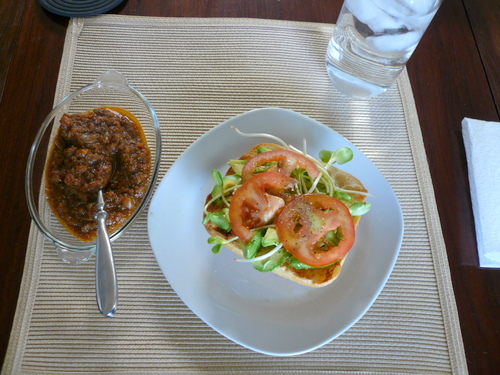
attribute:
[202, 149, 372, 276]
vegetable — green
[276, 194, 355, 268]
tomatoe — sliced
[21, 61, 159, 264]
bowl — glass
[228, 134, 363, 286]
tomatoes — sliced, red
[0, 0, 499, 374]
wooden table — wooden topped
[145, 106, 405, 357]
plate — white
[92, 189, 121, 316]
handle — silver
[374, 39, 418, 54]
ice — cold piece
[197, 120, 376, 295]
sandwich — healthy, open faced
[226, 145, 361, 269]
tomato — several slices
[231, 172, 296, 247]
tomato — vegetable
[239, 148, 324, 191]
tomato — vegetable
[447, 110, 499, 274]
napkin — white, folded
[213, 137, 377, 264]
vegetable — red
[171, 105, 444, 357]
bowl — white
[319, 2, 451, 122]
glass — ice water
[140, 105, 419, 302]
bread — sliced, on bottom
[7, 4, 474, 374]
place mat — beige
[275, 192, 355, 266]
red tomato — slice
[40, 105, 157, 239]
food — brown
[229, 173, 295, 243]
tomato — sliced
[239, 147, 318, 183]
tomato — sliced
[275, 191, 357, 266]
tomato — vegetable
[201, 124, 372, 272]
greens — micro